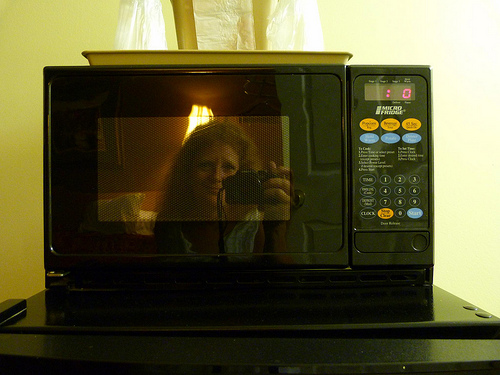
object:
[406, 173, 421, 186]
button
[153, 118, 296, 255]
woman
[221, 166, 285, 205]
camera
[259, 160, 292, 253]
hand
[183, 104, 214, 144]
light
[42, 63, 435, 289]
microwave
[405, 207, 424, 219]
button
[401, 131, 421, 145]
button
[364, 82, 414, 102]
digital indicator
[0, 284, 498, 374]
table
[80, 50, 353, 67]
pan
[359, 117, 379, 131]
button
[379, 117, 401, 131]
button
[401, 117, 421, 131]
button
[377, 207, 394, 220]
button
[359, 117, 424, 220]
control panel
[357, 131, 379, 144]
button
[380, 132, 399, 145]
button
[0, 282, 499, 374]
fridge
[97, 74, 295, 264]
image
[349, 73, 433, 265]
panel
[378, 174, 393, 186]
button